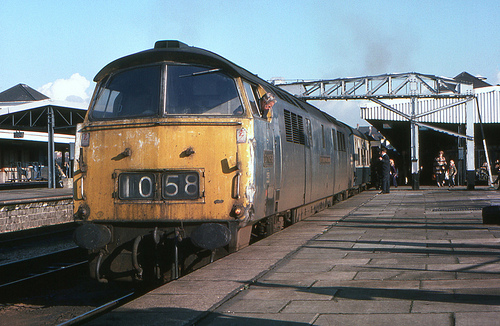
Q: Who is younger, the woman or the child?
A: The child is younger than the woman.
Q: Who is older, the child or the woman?
A: The woman is older than the child.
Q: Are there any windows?
A: Yes, there is a window.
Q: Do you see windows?
A: Yes, there is a window.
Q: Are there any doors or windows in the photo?
A: Yes, there is a window.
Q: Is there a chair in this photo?
A: No, there are no chairs.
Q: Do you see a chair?
A: No, there are no chairs.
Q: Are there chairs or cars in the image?
A: No, there are no chairs or cars.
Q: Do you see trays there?
A: No, there are no trays.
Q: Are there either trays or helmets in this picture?
A: No, there are no trays or helmets.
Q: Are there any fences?
A: No, there are no fences.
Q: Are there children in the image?
A: Yes, there is a child.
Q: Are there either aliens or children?
A: Yes, there is a child.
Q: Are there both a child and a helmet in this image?
A: No, there is a child but no helmets.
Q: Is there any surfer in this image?
A: No, there are no surfers.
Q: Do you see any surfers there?
A: No, there are no surfers.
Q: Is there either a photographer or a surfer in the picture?
A: No, there are no surfers or photographers.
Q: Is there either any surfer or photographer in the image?
A: No, there are no surfers or photographers.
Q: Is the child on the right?
A: Yes, the child is on the right of the image.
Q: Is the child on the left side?
A: No, the child is on the right of the image.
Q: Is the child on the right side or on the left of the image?
A: The child is on the right of the image.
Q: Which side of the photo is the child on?
A: The child is on the right of the image.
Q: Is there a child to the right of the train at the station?
A: Yes, there is a child to the right of the train.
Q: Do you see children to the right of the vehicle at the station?
A: Yes, there is a child to the right of the train.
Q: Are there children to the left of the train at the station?
A: No, the child is to the right of the train.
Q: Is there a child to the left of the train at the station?
A: No, the child is to the right of the train.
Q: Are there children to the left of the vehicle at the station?
A: No, the child is to the right of the train.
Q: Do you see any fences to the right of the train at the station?
A: No, there is a child to the right of the train.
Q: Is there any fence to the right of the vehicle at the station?
A: No, there is a child to the right of the train.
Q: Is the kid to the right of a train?
A: Yes, the kid is to the right of a train.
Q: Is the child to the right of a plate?
A: No, the child is to the right of a train.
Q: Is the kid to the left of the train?
A: No, the kid is to the right of the train.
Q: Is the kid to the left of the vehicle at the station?
A: No, the kid is to the right of the train.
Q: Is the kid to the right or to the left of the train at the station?
A: The kid is to the right of the train.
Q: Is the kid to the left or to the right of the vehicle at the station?
A: The kid is to the right of the train.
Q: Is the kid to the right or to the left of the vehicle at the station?
A: The kid is to the right of the train.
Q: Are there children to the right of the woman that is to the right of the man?
A: Yes, there is a child to the right of the woman.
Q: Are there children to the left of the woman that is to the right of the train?
A: No, the child is to the right of the woman.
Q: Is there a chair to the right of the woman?
A: No, there is a child to the right of the woman.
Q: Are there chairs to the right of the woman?
A: No, there is a child to the right of the woman.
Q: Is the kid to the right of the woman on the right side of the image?
A: Yes, the kid is to the right of the woman.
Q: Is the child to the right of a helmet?
A: No, the child is to the right of the woman.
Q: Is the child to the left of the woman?
A: No, the child is to the right of the woman.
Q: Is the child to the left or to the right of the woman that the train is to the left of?
A: The child is to the right of the woman.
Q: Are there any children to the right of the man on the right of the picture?
A: Yes, there is a child to the right of the man.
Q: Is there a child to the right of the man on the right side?
A: Yes, there is a child to the right of the man.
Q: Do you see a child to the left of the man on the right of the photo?
A: No, the child is to the right of the man.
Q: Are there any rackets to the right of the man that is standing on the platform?
A: No, there is a child to the right of the man.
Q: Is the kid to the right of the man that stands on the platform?
A: Yes, the kid is to the right of the man.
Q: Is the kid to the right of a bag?
A: No, the kid is to the right of the man.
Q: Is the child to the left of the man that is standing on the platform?
A: No, the child is to the right of the man.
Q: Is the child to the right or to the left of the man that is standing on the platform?
A: The child is to the right of the man.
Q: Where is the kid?
A: The kid is at the station.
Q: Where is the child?
A: The kid is at the station.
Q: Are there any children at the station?
A: Yes, there is a child at the station.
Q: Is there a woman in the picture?
A: Yes, there is a woman.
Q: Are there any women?
A: Yes, there is a woman.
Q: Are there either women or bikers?
A: Yes, there is a woman.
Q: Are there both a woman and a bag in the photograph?
A: No, there is a woman but no bags.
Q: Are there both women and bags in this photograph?
A: No, there is a woman but no bags.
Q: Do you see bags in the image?
A: No, there are no bags.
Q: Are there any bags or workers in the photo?
A: No, there are no bags or workers.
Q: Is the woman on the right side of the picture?
A: Yes, the woman is on the right of the image.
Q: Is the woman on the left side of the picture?
A: No, the woman is on the right of the image.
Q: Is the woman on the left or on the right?
A: The woman is on the right of the image.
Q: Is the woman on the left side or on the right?
A: The woman is on the right of the image.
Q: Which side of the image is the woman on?
A: The woman is on the right of the image.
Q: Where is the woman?
A: The woman is at the station.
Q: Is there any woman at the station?
A: Yes, there is a woman at the station.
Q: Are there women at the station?
A: Yes, there is a woman at the station.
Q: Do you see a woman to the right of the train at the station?
A: Yes, there is a woman to the right of the train.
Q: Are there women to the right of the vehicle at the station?
A: Yes, there is a woman to the right of the train.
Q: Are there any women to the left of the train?
A: No, the woman is to the right of the train.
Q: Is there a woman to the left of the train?
A: No, the woman is to the right of the train.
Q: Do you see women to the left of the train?
A: No, the woman is to the right of the train.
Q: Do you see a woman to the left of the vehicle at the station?
A: No, the woman is to the right of the train.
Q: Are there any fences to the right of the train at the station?
A: No, there is a woman to the right of the train.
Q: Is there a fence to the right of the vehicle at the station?
A: No, there is a woman to the right of the train.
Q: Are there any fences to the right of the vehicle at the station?
A: No, there is a woman to the right of the train.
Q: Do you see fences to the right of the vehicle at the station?
A: No, there is a woman to the right of the train.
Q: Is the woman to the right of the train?
A: Yes, the woman is to the right of the train.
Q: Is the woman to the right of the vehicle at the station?
A: Yes, the woman is to the right of the train.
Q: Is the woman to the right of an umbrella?
A: No, the woman is to the right of the train.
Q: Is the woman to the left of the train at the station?
A: No, the woman is to the right of the train.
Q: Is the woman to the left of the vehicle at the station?
A: No, the woman is to the right of the train.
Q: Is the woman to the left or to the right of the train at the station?
A: The woman is to the right of the train.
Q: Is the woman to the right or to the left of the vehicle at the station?
A: The woman is to the right of the train.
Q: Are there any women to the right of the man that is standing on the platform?
A: Yes, there is a woman to the right of the man.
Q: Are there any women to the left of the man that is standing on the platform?
A: No, the woman is to the right of the man.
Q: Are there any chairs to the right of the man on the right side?
A: No, there is a woman to the right of the man.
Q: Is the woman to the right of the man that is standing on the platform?
A: Yes, the woman is to the right of the man.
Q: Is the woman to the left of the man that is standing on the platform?
A: No, the woman is to the right of the man.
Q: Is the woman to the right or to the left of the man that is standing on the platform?
A: The woman is to the right of the man.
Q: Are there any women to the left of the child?
A: Yes, there is a woman to the left of the child.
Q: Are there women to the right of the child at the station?
A: No, the woman is to the left of the child.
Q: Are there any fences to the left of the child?
A: No, there is a woman to the left of the child.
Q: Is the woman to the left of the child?
A: Yes, the woman is to the left of the child.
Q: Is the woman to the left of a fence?
A: No, the woman is to the left of the child.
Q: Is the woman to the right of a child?
A: No, the woman is to the left of a child.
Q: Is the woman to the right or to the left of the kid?
A: The woman is to the left of the kid.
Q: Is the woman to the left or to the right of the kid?
A: The woman is to the left of the kid.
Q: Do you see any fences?
A: No, there are no fences.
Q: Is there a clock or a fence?
A: No, there are no fences or clocks.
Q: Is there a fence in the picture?
A: No, there are no fences.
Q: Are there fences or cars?
A: No, there are no fences or cars.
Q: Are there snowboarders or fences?
A: No, there are no fences or snowboarders.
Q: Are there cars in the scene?
A: No, there are no cars.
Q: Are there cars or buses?
A: No, there are no cars or buses.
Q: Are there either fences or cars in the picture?
A: No, there are no fences or cars.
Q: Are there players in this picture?
A: No, there are no players.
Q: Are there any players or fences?
A: No, there are no players or fences.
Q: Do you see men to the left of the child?
A: Yes, there is a man to the left of the child.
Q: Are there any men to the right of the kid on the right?
A: No, the man is to the left of the child.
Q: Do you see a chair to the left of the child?
A: No, there is a man to the left of the child.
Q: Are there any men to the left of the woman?
A: Yes, there is a man to the left of the woman.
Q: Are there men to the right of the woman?
A: No, the man is to the left of the woman.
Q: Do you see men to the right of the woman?
A: No, the man is to the left of the woman.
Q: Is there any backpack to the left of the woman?
A: No, there is a man to the left of the woman.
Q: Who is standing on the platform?
A: The man is standing on the platform.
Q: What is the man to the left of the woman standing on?
A: The man is standing on the platform.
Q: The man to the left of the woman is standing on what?
A: The man is standing on the platform.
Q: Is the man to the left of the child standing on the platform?
A: Yes, the man is standing on the platform.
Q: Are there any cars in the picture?
A: No, there are no cars.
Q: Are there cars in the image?
A: No, there are no cars.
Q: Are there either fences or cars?
A: No, there are no cars or fences.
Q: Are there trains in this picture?
A: Yes, there is a train.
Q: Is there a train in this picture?
A: Yes, there is a train.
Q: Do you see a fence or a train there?
A: Yes, there is a train.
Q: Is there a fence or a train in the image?
A: Yes, there is a train.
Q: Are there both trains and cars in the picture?
A: No, there is a train but no cars.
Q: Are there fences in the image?
A: No, there are no fences.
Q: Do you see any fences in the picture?
A: No, there are no fences.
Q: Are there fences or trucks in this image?
A: No, there are no fences or trucks.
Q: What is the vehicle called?
A: The vehicle is a train.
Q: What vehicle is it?
A: The vehicle is a train.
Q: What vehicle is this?
A: This is a train.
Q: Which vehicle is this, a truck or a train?
A: This is a train.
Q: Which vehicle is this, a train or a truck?
A: This is a train.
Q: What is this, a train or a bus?
A: This is a train.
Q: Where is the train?
A: The train is at the station.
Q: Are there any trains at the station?
A: Yes, there is a train at the station.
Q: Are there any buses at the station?
A: No, there is a train at the station.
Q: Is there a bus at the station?
A: No, there is a train at the station.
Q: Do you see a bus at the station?
A: No, there is a train at the station.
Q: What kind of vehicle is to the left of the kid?
A: The vehicle is a train.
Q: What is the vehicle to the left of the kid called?
A: The vehicle is a train.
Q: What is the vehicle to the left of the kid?
A: The vehicle is a train.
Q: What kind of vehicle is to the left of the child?
A: The vehicle is a train.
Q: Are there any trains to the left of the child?
A: Yes, there is a train to the left of the child.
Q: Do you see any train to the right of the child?
A: No, the train is to the left of the child.